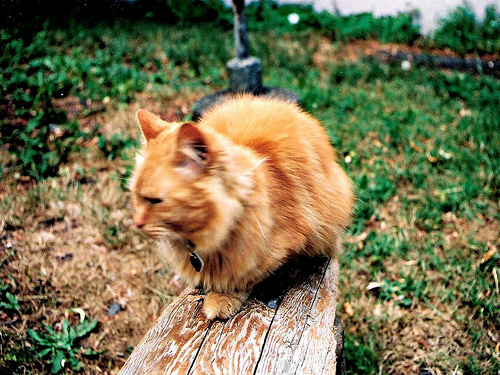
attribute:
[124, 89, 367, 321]
cat — sitting, furry, flufffy, orange, yellow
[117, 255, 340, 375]
log — brown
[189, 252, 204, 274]
tag — black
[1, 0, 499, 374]
ground — brown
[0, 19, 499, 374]
grass — brown, green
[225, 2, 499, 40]
sky — white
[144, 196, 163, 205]
eye — black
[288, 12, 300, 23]
bloom — white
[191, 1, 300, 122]
stand — black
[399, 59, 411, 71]
ball — white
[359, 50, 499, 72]
log — black